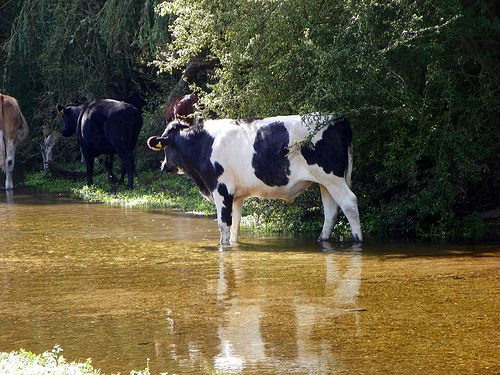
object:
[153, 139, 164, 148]
tag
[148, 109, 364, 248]
cow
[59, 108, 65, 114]
tag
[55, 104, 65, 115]
ear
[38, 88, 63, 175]
cow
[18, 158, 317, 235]
bank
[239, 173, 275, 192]
stomach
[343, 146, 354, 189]
tail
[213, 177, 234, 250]
leg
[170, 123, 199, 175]
neck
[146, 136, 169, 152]
ear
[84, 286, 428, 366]
surface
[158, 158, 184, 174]
mouth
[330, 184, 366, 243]
legs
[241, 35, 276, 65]
leaves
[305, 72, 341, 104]
leaves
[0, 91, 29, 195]
bull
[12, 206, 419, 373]
water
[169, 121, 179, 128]
horns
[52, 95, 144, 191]
bull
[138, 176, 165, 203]
grass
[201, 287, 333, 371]
reflection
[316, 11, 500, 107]
bush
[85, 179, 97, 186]
feet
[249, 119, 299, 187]
spots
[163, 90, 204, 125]
bull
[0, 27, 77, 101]
bushes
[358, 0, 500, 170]
trees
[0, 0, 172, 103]
trees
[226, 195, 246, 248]
legs